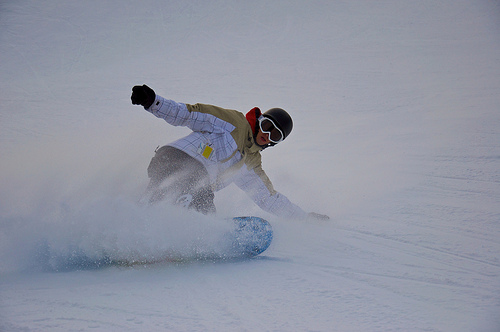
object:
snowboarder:
[80, 82, 327, 260]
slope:
[280, 3, 493, 318]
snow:
[1, 2, 496, 331]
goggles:
[257, 116, 285, 143]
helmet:
[263, 108, 293, 140]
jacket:
[143, 95, 305, 221]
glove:
[130, 84, 155, 106]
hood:
[245, 107, 262, 134]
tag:
[203, 145, 214, 160]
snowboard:
[40, 216, 272, 266]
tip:
[231, 216, 273, 257]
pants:
[148, 146, 218, 218]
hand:
[311, 212, 330, 223]